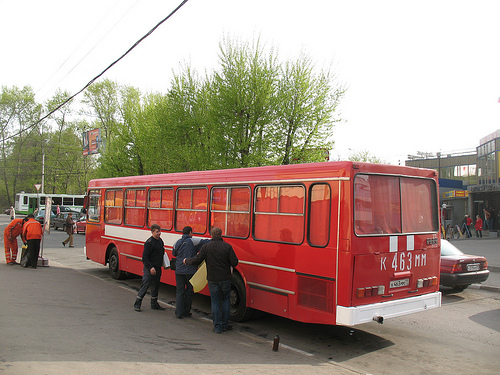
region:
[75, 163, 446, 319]
a large red and white bus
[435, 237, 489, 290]
part of a red car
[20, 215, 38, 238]
a man's orange jacket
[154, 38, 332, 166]
part of a large green tree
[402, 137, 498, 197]
part of a building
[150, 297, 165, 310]
a man's black shoe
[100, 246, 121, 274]
a black bus tire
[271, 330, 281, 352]
a brown drink bottle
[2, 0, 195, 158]
a black electrical power line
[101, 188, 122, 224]
the window of the bus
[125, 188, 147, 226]
the window of the bus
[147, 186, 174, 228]
the window of the bus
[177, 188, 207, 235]
the window of the bus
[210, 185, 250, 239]
the window of the bus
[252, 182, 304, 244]
the window of the bus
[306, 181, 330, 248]
the window of the bus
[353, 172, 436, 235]
the window of the bus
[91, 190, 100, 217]
the window of the bus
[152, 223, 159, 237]
the head of the man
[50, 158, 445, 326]
red bus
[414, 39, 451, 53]
white clouds in blue sky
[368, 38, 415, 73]
white clouds in blue sky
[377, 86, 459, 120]
white clouds in blue sky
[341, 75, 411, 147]
white clouds in blue sky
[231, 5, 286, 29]
white clouds in blue sky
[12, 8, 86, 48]
white clouds in blue sky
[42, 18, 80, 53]
white clouds in blue sky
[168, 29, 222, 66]
white clouds in blue sky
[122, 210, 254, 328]
three men standing near red bus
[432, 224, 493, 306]
burgundy car next to the red bus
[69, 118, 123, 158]
billboard mounted high near the trees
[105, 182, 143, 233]
red curtains in the bus window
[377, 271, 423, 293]
long skinny license plate on bus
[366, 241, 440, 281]
white numbers and letter painted on bus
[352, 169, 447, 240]
large rear window with curtains on bus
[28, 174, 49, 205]
red and white yield sign in distance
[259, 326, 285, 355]
glass bottle on the curb near the bus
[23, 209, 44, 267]
man in neon orange jacket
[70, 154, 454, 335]
the bus is color red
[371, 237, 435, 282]
number 463 on back the bus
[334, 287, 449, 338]
white bumper on bus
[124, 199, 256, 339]
three men on side the bus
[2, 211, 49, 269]
two men wears orange clothes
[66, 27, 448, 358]
three behind the red bus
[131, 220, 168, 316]
man wears black clothes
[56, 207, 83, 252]
the man is walking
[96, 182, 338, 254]
windows of bus are covered with red curtains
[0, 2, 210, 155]
power lines over the street